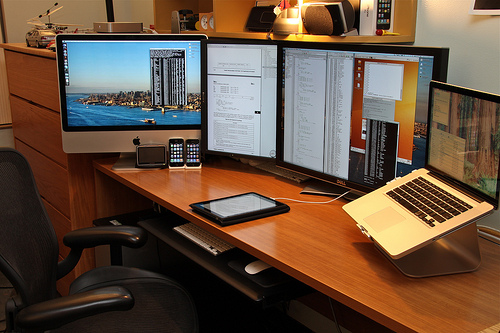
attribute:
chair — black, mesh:
[0, 145, 201, 332]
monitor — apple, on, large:
[54, 32, 208, 155]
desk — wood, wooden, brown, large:
[89, 153, 499, 332]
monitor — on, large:
[200, 37, 282, 164]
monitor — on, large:
[279, 40, 450, 194]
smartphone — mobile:
[135, 144, 168, 168]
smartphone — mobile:
[168, 136, 186, 168]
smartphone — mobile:
[183, 136, 201, 168]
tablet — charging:
[189, 191, 291, 226]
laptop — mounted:
[341, 79, 499, 260]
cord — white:
[273, 190, 351, 204]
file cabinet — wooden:
[1, 41, 97, 299]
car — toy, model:
[23, 28, 56, 50]